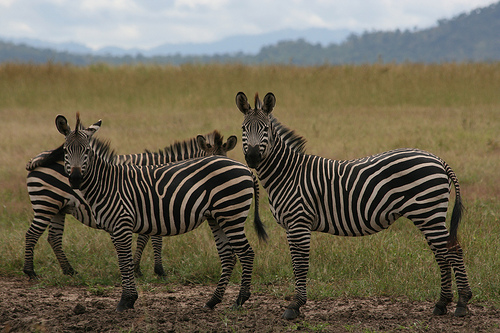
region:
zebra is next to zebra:
[233, 88, 474, 320]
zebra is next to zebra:
[26, 132, 238, 280]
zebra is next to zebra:
[55, 112, 270, 313]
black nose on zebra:
[242, 145, 263, 167]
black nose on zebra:
[68, 167, 80, 188]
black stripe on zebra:
[209, 178, 251, 208]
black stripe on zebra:
[209, 215, 250, 232]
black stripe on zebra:
[25, 167, 90, 224]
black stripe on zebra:
[155, 158, 206, 196]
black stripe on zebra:
[376, 175, 448, 229]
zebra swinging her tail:
[18, 113, 233, 308]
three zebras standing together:
[15, 92, 477, 319]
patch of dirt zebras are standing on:
[8, 281, 493, 332]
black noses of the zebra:
[68, 145, 260, 191]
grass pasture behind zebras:
[8, 66, 492, 288]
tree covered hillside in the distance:
[5, 10, 496, 66]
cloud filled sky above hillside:
[8, 5, 473, 57]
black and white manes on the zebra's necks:
[78, 111, 313, 172]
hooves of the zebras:
[29, 261, 474, 331]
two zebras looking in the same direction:
[50, 89, 472, 328]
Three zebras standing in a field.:
[20, 90, 467, 331]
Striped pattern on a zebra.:
[123, 170, 206, 219]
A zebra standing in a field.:
[236, 92, 472, 320]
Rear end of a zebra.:
[397, 145, 474, 318]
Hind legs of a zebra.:
[202, 209, 258, 309]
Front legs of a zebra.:
[271, 188, 309, 319]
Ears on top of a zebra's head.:
[235, 86, 276, 116]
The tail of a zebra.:
[443, 155, 462, 252]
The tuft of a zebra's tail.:
[252, 210, 269, 240]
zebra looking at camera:
[231, 83, 483, 326]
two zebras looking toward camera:
[55, 87, 478, 325]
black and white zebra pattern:
[302, 158, 394, 220]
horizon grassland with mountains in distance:
[10, 5, 497, 88]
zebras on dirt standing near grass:
[18, 84, 494, 331]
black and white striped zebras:
[23, 87, 479, 324]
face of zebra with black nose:
[231, 87, 280, 169]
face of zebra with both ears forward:
[233, 88, 280, 173]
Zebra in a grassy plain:
[13, 82, 479, 324]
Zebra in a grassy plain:
[11, 83, 488, 327]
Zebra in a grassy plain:
[8, 86, 475, 323]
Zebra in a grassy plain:
[11, 83, 483, 328]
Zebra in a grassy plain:
[11, 84, 474, 330]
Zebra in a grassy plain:
[12, 85, 479, 328]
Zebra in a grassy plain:
[18, 87, 480, 332]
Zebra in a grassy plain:
[17, 80, 483, 328]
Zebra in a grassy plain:
[17, 84, 475, 328]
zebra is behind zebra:
[235, 91, 472, 326]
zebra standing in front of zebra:
[47, 113, 267, 298]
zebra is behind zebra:
[23, 126, 236, 286]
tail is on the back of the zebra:
[250, 166, 268, 241]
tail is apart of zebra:
[440, 156, 462, 251]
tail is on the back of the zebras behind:
[25, 141, 65, 169]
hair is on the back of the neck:
[270, 112, 307, 149]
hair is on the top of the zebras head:
[71, 111, 113, 161]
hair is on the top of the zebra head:
[141, 127, 221, 149]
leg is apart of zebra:
[284, 227, 310, 319]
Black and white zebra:
[233, 88, 471, 330]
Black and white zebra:
[50, 109, 266, 315]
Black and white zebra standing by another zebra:
[232, 85, 472, 318]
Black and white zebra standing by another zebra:
[52, 108, 268, 316]